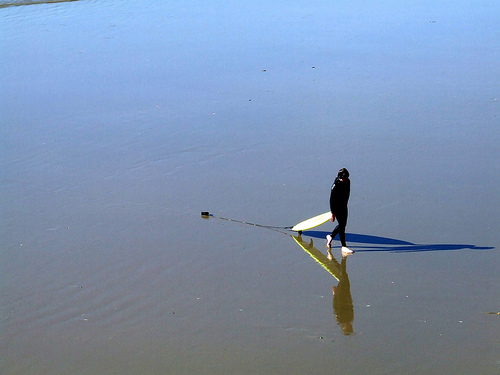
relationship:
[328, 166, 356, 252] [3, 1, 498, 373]
person walking in watered area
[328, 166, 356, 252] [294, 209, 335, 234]
person has surfboard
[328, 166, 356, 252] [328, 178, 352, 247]
person wearing wet suit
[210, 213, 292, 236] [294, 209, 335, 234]
rope trailing behind surfboard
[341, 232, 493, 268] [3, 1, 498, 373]
reflection of person seen in watered area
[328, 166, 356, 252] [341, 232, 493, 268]
person has reflection of person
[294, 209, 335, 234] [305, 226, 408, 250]
surfboard has shadow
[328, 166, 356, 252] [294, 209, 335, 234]
person dragging surfboard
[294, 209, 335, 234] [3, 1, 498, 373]
surfboard in watered area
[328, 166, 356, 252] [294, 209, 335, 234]
person carrying surfboard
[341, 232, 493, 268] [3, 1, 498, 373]
reflection of person across watered area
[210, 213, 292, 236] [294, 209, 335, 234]
rope attached to surfboard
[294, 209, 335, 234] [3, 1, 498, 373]
surfboard on top of watered area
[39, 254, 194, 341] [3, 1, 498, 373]
sand ripples under watered area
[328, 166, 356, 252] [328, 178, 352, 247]
person has wet suit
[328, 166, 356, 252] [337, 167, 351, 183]
person has hair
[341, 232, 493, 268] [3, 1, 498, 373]
reflection of person on top of watered area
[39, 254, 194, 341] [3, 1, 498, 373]
sand ripples show through watered area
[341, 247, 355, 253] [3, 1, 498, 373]
foot walking on watered area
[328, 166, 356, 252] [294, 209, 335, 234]
person holding surfboard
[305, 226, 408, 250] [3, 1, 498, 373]
shadow across watered area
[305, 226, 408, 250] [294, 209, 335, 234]
shadow of surfboard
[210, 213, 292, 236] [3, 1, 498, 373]
rope on top of watered area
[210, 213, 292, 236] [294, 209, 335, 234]
rope behind surfboard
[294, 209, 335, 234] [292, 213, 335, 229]
surfboard has top